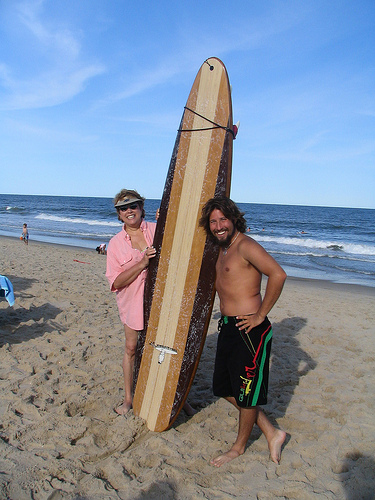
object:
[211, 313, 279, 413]
swim trunks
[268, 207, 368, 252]
ocean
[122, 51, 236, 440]
surfboard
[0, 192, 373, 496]
beach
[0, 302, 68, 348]
shadow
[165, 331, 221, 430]
shadow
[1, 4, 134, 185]
clouds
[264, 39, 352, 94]
clouds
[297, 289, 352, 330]
sand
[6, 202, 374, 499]
ground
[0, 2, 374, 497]
picture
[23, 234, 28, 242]
short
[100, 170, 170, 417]
woman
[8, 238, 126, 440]
coast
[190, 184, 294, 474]
man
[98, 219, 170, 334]
pink shirt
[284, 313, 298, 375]
sand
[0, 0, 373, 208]
blue sky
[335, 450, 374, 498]
shadow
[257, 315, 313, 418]
shadow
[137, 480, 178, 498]
shadow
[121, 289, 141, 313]
pink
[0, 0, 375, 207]
sky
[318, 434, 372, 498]
sand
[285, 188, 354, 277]
water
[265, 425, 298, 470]
foot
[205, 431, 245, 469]
foot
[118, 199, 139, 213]
sunglasses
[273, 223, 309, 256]
waves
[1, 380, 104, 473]
sand